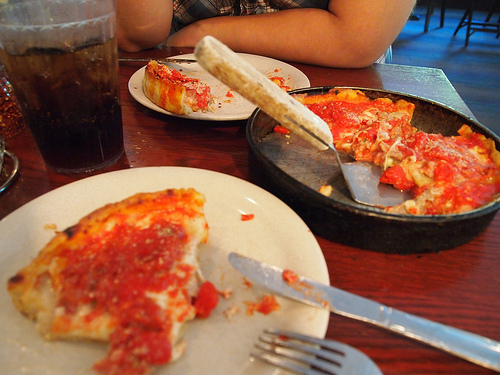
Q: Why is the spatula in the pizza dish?
A: To serve it.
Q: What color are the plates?
A: White.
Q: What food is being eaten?
A: Pizza.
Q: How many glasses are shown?
A: One.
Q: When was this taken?
A: During mealtime.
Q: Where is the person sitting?
A: At the table.